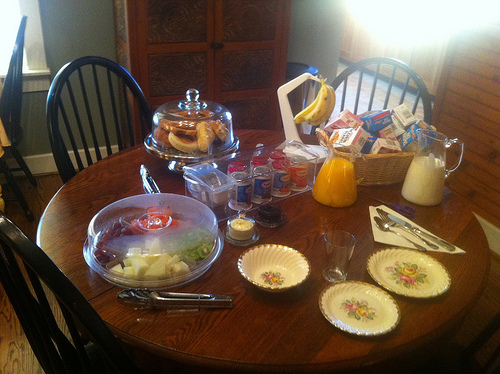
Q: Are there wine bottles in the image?
A: No, there are no wine bottles.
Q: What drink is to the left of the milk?
A: The drink is juice.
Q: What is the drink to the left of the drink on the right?
A: The drink is juice.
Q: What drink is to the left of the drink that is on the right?
A: The drink is juice.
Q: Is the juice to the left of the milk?
A: Yes, the juice is to the left of the milk.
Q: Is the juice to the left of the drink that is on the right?
A: Yes, the juice is to the left of the milk.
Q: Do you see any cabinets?
A: Yes, there is a cabinet.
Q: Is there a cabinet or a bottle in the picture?
A: Yes, there is a cabinet.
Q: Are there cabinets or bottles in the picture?
A: Yes, there is a cabinet.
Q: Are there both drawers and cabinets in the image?
A: No, there is a cabinet but no drawers.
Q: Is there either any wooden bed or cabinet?
A: Yes, there is a wood cabinet.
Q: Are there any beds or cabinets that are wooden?
A: Yes, the cabinet is wooden.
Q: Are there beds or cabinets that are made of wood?
A: Yes, the cabinet is made of wood.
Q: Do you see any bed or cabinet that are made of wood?
A: Yes, the cabinet is made of wood.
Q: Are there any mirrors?
A: No, there are no mirrors.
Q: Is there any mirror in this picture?
A: No, there are no mirrors.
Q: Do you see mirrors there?
A: No, there are no mirrors.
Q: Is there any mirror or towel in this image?
A: No, there are no mirrors or towels.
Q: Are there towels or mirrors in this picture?
A: No, there are no mirrors or towels.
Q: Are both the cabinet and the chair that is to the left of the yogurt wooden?
A: Yes, both the cabinet and the chair are wooden.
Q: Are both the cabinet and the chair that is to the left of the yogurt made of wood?
A: Yes, both the cabinet and the chair are made of wood.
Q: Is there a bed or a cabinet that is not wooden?
A: No, there is a cabinet but it is wooden.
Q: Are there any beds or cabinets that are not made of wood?
A: No, there is a cabinet but it is made of wood.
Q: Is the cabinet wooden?
A: Yes, the cabinet is wooden.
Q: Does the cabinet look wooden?
A: Yes, the cabinet is wooden.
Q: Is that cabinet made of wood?
A: Yes, the cabinet is made of wood.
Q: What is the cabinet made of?
A: The cabinet is made of wood.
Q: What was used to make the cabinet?
A: The cabinet is made of wood.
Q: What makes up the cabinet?
A: The cabinet is made of wood.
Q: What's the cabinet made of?
A: The cabinet is made of wood.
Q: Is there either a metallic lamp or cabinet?
A: No, there is a cabinet but it is wooden.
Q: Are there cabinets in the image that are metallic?
A: No, there is a cabinet but it is wooden.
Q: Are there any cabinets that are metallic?
A: No, there is a cabinet but it is wooden.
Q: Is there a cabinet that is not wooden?
A: No, there is a cabinet but it is wooden.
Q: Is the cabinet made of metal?
A: No, the cabinet is made of wood.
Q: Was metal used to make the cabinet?
A: No, the cabinet is made of wood.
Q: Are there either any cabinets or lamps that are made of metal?
A: No, there is a cabinet but it is made of wood.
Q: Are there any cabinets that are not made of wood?
A: No, there is a cabinet but it is made of wood.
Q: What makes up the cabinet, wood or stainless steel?
A: The cabinet is made of wood.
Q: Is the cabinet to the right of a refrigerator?
A: No, the cabinet is to the right of a chair.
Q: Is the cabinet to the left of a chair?
A: No, the cabinet is to the right of a chair.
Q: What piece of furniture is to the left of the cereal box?
A: The piece of furniture is a cabinet.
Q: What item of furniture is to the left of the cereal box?
A: The piece of furniture is a cabinet.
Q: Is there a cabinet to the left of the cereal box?
A: Yes, there is a cabinet to the left of the cereal box.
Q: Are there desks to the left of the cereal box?
A: No, there is a cabinet to the left of the cereal box.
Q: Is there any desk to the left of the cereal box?
A: No, there is a cabinet to the left of the cereal box.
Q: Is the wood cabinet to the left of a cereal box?
A: Yes, the cabinet is to the left of a cereal box.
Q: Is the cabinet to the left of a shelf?
A: No, the cabinet is to the left of a cereal box.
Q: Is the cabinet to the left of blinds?
A: No, the cabinet is to the left of the bananas.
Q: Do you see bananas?
A: Yes, there are bananas.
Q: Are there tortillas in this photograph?
A: No, there are no tortillas.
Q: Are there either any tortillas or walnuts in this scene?
A: No, there are no tortillas or walnuts.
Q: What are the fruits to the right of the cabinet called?
A: The fruits are bananas.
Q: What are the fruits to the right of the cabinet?
A: The fruits are bananas.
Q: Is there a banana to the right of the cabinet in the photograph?
A: Yes, there are bananas to the right of the cabinet.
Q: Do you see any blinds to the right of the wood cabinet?
A: No, there are bananas to the right of the cabinet.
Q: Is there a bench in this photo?
A: No, there are no benches.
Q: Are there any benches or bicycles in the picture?
A: No, there are no benches or bicycles.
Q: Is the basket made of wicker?
A: Yes, the basket is made of wicker.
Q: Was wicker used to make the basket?
A: Yes, the basket is made of wicker.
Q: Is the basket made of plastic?
A: No, the basket is made of wicker.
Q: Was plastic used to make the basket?
A: No, the basket is made of wicker.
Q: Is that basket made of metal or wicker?
A: The basket is made of wicker.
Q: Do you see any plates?
A: Yes, there is a plate.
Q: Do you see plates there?
A: Yes, there is a plate.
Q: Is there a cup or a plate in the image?
A: Yes, there is a plate.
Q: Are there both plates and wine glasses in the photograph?
A: No, there is a plate but no wine glasses.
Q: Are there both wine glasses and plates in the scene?
A: No, there is a plate but no wine glasses.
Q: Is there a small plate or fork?
A: Yes, there is a small plate.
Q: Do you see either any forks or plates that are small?
A: Yes, the plate is small.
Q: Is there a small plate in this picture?
A: Yes, there is a small plate.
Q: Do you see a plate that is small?
A: Yes, there is a plate that is small.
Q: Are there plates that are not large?
A: Yes, there is a small plate.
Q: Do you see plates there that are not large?
A: Yes, there is a small plate.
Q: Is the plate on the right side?
A: Yes, the plate is on the right of the image.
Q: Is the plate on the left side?
A: No, the plate is on the right of the image.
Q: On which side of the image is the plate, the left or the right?
A: The plate is on the right of the image.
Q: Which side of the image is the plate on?
A: The plate is on the right of the image.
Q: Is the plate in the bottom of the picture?
A: Yes, the plate is in the bottom of the image.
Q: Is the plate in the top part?
A: No, the plate is in the bottom of the image.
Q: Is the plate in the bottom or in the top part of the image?
A: The plate is in the bottom of the image.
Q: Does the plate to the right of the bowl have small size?
A: Yes, the plate is small.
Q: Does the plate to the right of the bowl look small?
A: Yes, the plate is small.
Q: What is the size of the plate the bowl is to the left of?
A: The plate is small.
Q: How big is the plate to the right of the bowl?
A: The plate is small.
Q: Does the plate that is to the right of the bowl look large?
A: No, the plate is small.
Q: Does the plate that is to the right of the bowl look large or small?
A: The plate is small.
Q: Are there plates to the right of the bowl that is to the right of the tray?
A: Yes, there is a plate to the right of the bowl.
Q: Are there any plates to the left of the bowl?
A: No, the plate is to the right of the bowl.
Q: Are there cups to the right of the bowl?
A: No, there is a plate to the right of the bowl.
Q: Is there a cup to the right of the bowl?
A: No, there is a plate to the right of the bowl.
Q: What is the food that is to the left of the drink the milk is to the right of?
A: The food is yogurt.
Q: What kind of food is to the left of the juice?
A: The food is yogurt.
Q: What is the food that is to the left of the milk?
A: The food is yogurt.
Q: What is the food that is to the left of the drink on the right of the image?
A: The food is yogurt.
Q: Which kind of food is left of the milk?
A: The food is yogurt.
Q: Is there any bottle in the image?
A: No, there are no bottles.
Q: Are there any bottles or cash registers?
A: No, there are no bottles or cash registers.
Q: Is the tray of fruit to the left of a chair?
A: No, the tray is to the right of a chair.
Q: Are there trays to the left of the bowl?
A: Yes, there is a tray to the left of the bowl.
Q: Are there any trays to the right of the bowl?
A: No, the tray is to the left of the bowl.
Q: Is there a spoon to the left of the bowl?
A: No, there is a tray to the left of the bowl.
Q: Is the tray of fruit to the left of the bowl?
A: Yes, the tray is to the left of the bowl.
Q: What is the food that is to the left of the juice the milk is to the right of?
A: The food is yogurt.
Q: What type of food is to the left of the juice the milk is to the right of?
A: The food is yogurt.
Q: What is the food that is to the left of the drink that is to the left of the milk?
A: The food is yogurt.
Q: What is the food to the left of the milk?
A: The food is yogurt.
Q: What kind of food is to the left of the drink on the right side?
A: The food is yogurt.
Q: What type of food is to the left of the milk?
A: The food is yogurt.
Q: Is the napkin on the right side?
A: Yes, the napkin is on the right of the image.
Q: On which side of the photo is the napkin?
A: The napkin is on the right of the image.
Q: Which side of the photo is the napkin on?
A: The napkin is on the right of the image.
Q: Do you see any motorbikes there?
A: No, there are no motorbikes.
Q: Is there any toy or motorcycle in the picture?
A: No, there are no motorcycles or toys.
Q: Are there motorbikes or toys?
A: No, there are no motorbikes or toys.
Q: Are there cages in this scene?
A: No, there are no cages.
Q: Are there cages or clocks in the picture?
A: No, there are no cages or clocks.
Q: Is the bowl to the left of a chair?
A: No, the bowl is to the right of a chair.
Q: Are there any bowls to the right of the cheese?
A: Yes, there is a bowl to the right of the cheese.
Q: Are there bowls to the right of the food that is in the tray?
A: Yes, there is a bowl to the right of the cheese.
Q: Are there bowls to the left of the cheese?
A: No, the bowl is to the right of the cheese.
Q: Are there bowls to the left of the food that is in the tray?
A: No, the bowl is to the right of the cheese.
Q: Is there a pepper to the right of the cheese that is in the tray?
A: No, there is a bowl to the right of the cheese.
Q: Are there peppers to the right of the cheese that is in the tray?
A: No, there is a bowl to the right of the cheese.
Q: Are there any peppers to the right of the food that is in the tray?
A: No, there is a bowl to the right of the cheese.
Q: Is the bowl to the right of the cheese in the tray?
A: Yes, the bowl is to the right of the cheese.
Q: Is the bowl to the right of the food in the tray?
A: Yes, the bowl is to the right of the cheese.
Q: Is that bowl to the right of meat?
A: No, the bowl is to the right of the cheese.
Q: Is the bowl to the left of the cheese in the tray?
A: No, the bowl is to the right of the cheese.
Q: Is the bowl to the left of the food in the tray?
A: No, the bowl is to the right of the cheese.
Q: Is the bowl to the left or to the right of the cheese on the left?
A: The bowl is to the right of the cheese.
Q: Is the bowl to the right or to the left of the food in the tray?
A: The bowl is to the right of the cheese.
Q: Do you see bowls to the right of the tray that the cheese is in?
A: Yes, there is a bowl to the right of the tray.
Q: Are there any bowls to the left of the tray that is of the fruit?
A: No, the bowl is to the right of the tray.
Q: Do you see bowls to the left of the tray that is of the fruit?
A: No, the bowl is to the right of the tray.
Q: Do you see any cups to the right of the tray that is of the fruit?
A: No, there is a bowl to the right of the tray.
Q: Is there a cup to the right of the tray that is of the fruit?
A: No, there is a bowl to the right of the tray.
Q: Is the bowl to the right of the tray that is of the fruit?
A: Yes, the bowl is to the right of the tray.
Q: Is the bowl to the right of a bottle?
A: No, the bowl is to the right of the tray.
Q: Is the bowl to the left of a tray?
A: No, the bowl is to the right of a tray.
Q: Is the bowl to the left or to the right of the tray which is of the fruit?
A: The bowl is to the right of the tray.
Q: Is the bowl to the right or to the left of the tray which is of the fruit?
A: The bowl is to the right of the tray.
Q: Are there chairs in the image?
A: Yes, there is a chair.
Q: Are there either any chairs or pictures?
A: Yes, there is a chair.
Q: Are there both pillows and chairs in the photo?
A: No, there is a chair but no pillows.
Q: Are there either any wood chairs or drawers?
A: Yes, there is a wood chair.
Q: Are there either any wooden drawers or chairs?
A: Yes, there is a wood chair.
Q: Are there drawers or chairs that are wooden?
A: Yes, the chair is wooden.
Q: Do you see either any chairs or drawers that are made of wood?
A: Yes, the chair is made of wood.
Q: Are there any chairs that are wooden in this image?
A: Yes, there is a wood chair.